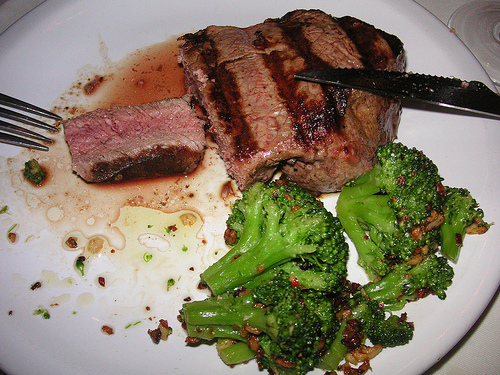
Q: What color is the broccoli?
A: Green.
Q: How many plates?
A: One.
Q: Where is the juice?
A: Under the meat.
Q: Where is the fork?
A: Side of plate.